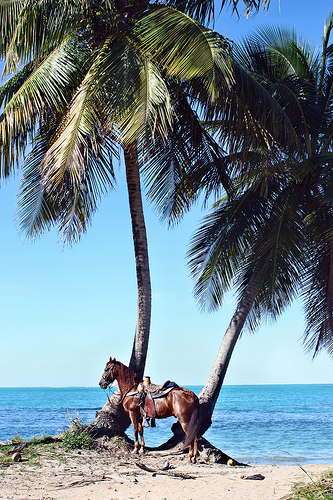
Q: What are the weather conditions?
A: It is clear.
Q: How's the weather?
A: It is clear.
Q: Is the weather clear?
A: Yes, it is clear.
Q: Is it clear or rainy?
A: It is clear.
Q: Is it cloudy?
A: No, it is clear.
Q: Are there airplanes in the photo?
A: No, there are no airplanes.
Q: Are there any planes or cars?
A: No, there are no planes or cars.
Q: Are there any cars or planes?
A: No, there are no planes or cars.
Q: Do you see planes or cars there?
A: No, there are no planes or cars.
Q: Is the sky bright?
A: Yes, the sky is bright.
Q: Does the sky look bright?
A: Yes, the sky is bright.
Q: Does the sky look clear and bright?
A: Yes, the sky is clear and bright.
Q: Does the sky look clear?
A: Yes, the sky is clear.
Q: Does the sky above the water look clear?
A: Yes, the sky is clear.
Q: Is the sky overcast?
A: No, the sky is clear.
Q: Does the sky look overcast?
A: No, the sky is clear.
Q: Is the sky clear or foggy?
A: The sky is clear.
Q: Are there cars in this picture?
A: No, there are no cars.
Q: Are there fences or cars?
A: No, there are no cars or fences.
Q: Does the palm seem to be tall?
A: Yes, the palm is tall.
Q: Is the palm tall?
A: Yes, the palm is tall.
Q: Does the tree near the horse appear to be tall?
A: Yes, the palm is tall.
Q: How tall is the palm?
A: The palm is tall.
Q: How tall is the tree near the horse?
A: The palm is tall.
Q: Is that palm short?
A: No, the palm is tall.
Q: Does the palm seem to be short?
A: No, the palm is tall.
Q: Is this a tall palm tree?
A: Yes, this is a tall palm tree.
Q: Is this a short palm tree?
A: No, this is a tall palm tree.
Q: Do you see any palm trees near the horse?
A: Yes, there is a palm tree near the horse.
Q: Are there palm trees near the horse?
A: Yes, there is a palm tree near the horse.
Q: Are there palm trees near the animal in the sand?
A: Yes, there is a palm tree near the horse.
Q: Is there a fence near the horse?
A: No, there is a palm tree near the horse.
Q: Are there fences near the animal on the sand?
A: No, there is a palm tree near the horse.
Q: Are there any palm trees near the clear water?
A: Yes, there is a palm tree near the water.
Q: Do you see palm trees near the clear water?
A: Yes, there is a palm tree near the water.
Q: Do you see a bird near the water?
A: No, there is a palm tree near the water.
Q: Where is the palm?
A: The palm is on the sand.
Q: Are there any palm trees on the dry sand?
A: Yes, there is a palm tree on the sand.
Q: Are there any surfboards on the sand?
A: No, there is a palm tree on the sand.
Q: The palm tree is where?
A: The palm tree is in the sand.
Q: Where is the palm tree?
A: The palm tree is in the sand.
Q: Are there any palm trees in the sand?
A: Yes, there is a palm tree in the sand.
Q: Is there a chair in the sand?
A: No, there is a palm tree in the sand.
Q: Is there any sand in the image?
A: Yes, there is sand.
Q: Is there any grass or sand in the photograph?
A: Yes, there is sand.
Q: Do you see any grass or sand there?
A: Yes, there is sand.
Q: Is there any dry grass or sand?
A: Yes, there is dry sand.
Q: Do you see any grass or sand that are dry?
A: Yes, the sand is dry.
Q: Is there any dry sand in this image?
A: Yes, there is dry sand.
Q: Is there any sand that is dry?
A: Yes, there is sand that is dry.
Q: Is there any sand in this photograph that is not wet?
A: Yes, there is dry sand.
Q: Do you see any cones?
A: No, there are no cones.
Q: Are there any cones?
A: No, there are no cones.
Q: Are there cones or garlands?
A: No, there are no cones or garlands.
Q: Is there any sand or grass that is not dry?
A: No, there is sand but it is dry.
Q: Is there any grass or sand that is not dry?
A: No, there is sand but it is dry.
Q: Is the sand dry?
A: Yes, the sand is dry.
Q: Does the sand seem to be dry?
A: Yes, the sand is dry.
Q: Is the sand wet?
A: No, the sand is dry.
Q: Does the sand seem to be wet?
A: No, the sand is dry.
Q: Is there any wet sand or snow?
A: No, there is sand but it is dry.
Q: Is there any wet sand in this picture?
A: No, there is sand but it is dry.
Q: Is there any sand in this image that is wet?
A: No, there is sand but it is dry.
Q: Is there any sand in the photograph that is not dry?
A: No, there is sand but it is dry.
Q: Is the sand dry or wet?
A: The sand is dry.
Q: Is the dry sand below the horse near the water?
A: Yes, the sand is below the horse.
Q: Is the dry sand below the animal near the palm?
A: Yes, the sand is below the horse.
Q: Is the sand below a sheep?
A: No, the sand is below the horse.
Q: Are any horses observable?
A: Yes, there is a horse.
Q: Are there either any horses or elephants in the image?
A: Yes, there is a horse.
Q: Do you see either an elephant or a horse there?
A: Yes, there is a horse.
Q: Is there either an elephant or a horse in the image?
A: Yes, there is a horse.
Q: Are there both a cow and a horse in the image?
A: No, there is a horse but no cows.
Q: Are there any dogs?
A: No, there are no dogs.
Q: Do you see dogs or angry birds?
A: No, there are no dogs or angry birds.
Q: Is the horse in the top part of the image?
A: No, the horse is in the bottom of the image.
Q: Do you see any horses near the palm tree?
A: Yes, there is a horse near the palm tree.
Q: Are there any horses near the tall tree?
A: Yes, there is a horse near the palm tree.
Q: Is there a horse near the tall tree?
A: Yes, there is a horse near the palm tree.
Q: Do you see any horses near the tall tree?
A: Yes, there is a horse near the palm tree.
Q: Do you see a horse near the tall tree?
A: Yes, there is a horse near the palm tree.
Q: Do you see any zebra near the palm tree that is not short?
A: No, there is a horse near the palm.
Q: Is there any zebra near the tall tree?
A: No, there is a horse near the palm.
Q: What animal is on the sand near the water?
A: The animal is a horse.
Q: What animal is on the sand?
A: The animal is a horse.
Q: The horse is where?
A: The horse is on the sand.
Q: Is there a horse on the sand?
A: Yes, there is a horse on the sand.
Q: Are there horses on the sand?
A: Yes, there is a horse on the sand.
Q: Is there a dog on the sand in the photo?
A: No, there is a horse on the sand.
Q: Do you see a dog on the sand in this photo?
A: No, there is a horse on the sand.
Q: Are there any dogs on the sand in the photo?
A: No, there is a horse on the sand.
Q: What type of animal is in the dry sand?
A: The animal is a horse.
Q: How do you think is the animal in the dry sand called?
A: The animal is a horse.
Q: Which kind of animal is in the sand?
A: The animal is a horse.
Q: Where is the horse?
A: The horse is in the sand.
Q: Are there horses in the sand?
A: Yes, there is a horse in the sand.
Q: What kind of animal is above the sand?
A: The animal is a horse.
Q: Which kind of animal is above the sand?
A: The animal is a horse.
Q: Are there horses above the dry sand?
A: Yes, there is a horse above the sand.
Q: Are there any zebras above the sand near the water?
A: No, there is a horse above the sand.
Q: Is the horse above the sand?
A: Yes, the horse is above the sand.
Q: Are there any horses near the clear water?
A: Yes, there is a horse near the water.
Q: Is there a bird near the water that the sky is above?
A: No, there is a horse near the water.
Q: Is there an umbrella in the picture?
A: No, there are no umbrellas.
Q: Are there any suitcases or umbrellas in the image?
A: No, there are no umbrellas or suitcases.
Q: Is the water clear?
A: Yes, the water is clear.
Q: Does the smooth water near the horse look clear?
A: Yes, the water is clear.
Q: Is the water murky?
A: No, the water is clear.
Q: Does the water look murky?
A: No, the water is clear.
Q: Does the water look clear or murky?
A: The water is clear.